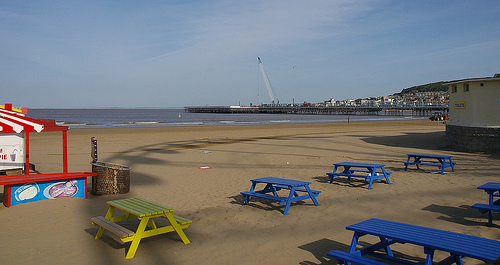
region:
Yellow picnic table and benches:
[88, 192, 195, 260]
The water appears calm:
[19, 105, 451, 130]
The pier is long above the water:
[181, 100, 450, 119]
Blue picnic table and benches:
[323, 157, 395, 191]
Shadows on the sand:
[95, 128, 498, 263]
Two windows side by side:
[449, 78, 474, 97]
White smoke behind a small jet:
[255, 54, 279, 105]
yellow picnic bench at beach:
[88, 197, 195, 258]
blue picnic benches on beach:
[235, 151, 499, 263]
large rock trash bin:
[89, 134, 131, 194]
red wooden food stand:
[0, 107, 97, 209]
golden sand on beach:
[1, 117, 498, 264]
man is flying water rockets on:
[256, 55, 279, 107]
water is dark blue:
[13, 108, 450, 127]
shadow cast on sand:
[93, 128, 497, 261]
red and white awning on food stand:
[0, 105, 52, 135]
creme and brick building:
[441, 71, 499, 153]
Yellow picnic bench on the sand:
[89, 193, 193, 259]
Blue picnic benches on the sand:
[238, 147, 496, 263]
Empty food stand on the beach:
[1, 105, 96, 212]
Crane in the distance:
[256, 52, 283, 114]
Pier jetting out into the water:
[180, 99, 451, 118]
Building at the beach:
[443, 75, 497, 148]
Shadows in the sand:
[111, 121, 497, 200]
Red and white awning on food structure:
[0, 103, 70, 139]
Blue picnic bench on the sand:
[238, 173, 323, 216]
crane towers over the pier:
[254, 53, 279, 103]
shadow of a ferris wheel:
[80, 124, 380, 239]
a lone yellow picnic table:
[88, 190, 190, 256]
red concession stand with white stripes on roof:
[1, 110, 96, 207]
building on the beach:
[439, 77, 499, 155]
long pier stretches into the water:
[181, 103, 443, 114]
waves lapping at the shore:
[55, 115, 414, 135]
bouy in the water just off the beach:
[175, 110, 185, 122]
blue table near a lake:
[396, 147, 451, 177]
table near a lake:
[321, 158, 401, 196]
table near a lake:
[225, 163, 337, 214]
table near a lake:
[326, 210, 489, 255]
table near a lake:
[455, 173, 496, 218]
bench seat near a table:
[90, 210, 131, 250]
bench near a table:
[232, 190, 297, 211]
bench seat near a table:
[326, 168, 376, 188]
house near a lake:
[7, 100, 75, 182]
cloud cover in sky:
[0, 1, 499, 106]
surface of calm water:
[21, 109, 409, 127]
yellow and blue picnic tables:
[91, 154, 497, 264]